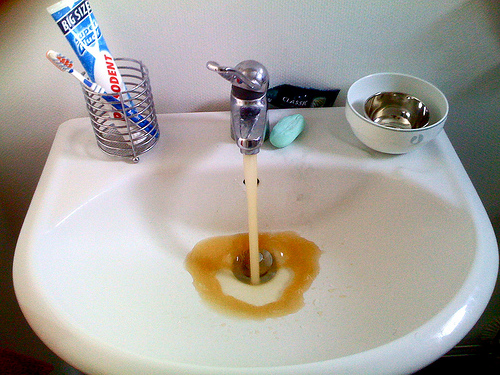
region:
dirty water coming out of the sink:
[176, 165, 326, 318]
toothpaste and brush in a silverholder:
[53, 5, 157, 167]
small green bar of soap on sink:
[273, 109, 313, 154]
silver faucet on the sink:
[211, 48, 269, 148]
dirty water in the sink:
[194, 240, 316, 308]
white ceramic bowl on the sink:
[331, 68, 449, 160]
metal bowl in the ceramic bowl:
[363, 83, 438, 136]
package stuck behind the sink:
[269, 82, 336, 110]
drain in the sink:
[231, 249, 275, 279]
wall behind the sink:
[294, 10, 411, 54]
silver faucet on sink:
[201, 61, 273, 158]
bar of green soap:
[267, 103, 309, 154]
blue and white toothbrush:
[32, 36, 164, 146]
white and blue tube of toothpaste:
[45, 0, 140, 151]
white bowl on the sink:
[340, 66, 451, 161]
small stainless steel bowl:
[360, 92, 428, 134]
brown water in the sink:
[184, 148, 326, 320]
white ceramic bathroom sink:
[17, 102, 497, 367]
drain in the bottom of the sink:
[235, 239, 277, 290]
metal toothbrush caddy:
[75, 56, 160, 168]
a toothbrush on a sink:
[41, 48, 146, 133]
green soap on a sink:
[268, 96, 331, 156]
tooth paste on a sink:
[41, 1, 136, 113]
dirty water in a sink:
[191, 189, 336, 314]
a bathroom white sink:
[30, 115, 487, 352]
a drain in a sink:
[216, 215, 323, 294]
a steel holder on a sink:
[79, 48, 184, 157]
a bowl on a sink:
[331, 57, 485, 169]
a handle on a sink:
[207, 42, 303, 124]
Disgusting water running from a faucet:
[222, 143, 338, 328]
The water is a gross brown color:
[238, 148, 275, 252]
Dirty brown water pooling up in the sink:
[190, 220, 336, 327]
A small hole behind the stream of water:
[239, 175, 264, 195]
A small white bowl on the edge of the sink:
[344, 69, 454, 165]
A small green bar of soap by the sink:
[261, 106, 312, 151]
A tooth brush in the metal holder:
[41, 47, 157, 130]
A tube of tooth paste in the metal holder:
[60, 0, 145, 115]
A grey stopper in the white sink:
[243, 250, 279, 272]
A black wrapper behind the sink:
[270, 85, 336, 110]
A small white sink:
[32, 95, 492, 372]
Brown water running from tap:
[204, 147, 310, 309]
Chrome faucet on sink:
[205, 54, 272, 170]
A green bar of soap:
[262, 112, 307, 143]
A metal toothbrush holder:
[70, 47, 161, 172]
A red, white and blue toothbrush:
[48, 46, 145, 136]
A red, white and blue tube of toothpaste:
[55, 3, 140, 128]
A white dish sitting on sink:
[338, 63, 456, 164]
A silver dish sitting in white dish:
[365, 85, 426, 128]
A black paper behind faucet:
[264, 83, 334, 109]